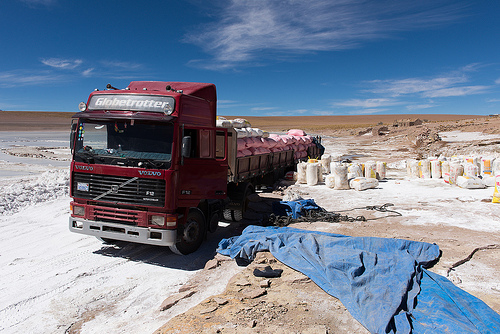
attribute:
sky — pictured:
[10, 8, 493, 73]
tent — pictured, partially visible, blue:
[224, 218, 497, 334]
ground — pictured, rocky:
[231, 276, 308, 327]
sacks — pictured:
[297, 157, 489, 193]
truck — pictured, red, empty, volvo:
[67, 120, 184, 239]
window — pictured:
[177, 127, 204, 159]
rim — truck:
[185, 218, 202, 246]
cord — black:
[267, 204, 403, 225]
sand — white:
[0, 180, 64, 327]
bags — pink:
[238, 130, 309, 158]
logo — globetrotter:
[89, 91, 174, 116]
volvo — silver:
[74, 162, 165, 177]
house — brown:
[490, 113, 500, 120]